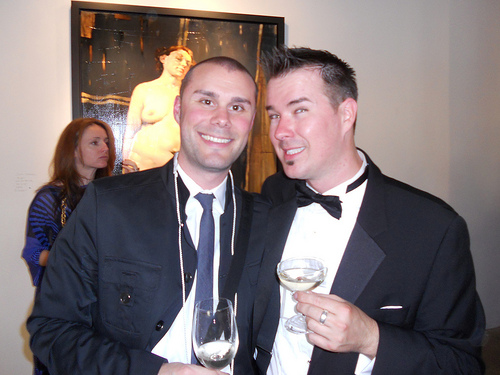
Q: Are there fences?
A: No, there are no fences.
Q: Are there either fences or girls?
A: No, there are no fences or girls.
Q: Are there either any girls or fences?
A: No, there are no fences or girls.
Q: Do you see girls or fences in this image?
A: No, there are no fences or girls.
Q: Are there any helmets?
A: No, there are no helmets.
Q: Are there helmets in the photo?
A: No, there are no helmets.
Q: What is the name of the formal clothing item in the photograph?
A: The clothing item is a suit.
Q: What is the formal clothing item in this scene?
A: The clothing item is a suit.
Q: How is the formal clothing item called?
A: The clothing item is a suit.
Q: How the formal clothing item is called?
A: The clothing item is a suit.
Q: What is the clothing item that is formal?
A: The clothing item is a suit.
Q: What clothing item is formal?
A: The clothing item is a suit.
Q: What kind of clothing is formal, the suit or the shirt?
A: The suit is formal.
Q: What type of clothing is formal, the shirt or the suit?
A: The suit is formal.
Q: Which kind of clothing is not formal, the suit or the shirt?
A: The shirt is not formal.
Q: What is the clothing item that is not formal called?
A: The clothing item is a shirt.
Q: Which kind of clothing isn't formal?
A: The clothing is a shirt.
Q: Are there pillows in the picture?
A: No, there are no pillows.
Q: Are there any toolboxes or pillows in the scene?
A: No, there are no pillows or toolboxes.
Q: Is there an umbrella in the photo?
A: No, there are no umbrellas.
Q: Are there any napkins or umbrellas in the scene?
A: No, there are no umbrellas or napkins.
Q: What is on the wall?
A: The picture is on the wall.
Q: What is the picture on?
A: The picture is on the wall.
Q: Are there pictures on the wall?
A: Yes, there is a picture on the wall.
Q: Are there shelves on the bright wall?
A: No, there is a picture on the wall.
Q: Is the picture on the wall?
A: Yes, the picture is on the wall.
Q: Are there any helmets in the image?
A: No, there are no helmets.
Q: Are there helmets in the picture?
A: No, there are no helmets.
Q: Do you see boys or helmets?
A: No, there are no helmets or boys.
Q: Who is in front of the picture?
A: The man is in front of the picture.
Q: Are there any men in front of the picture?
A: Yes, there is a man in front of the picture.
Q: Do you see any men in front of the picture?
A: Yes, there is a man in front of the picture.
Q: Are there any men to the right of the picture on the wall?
A: Yes, there is a man to the right of the picture.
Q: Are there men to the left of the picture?
A: No, the man is to the right of the picture.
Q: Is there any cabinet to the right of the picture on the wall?
A: No, there is a man to the right of the picture.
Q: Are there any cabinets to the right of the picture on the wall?
A: No, there is a man to the right of the picture.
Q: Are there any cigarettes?
A: No, there are no cigarettes.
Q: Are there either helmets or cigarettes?
A: No, there are no cigarettes or helmets.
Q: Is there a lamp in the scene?
A: No, there are no lamps.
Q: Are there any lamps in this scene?
A: No, there are no lamps.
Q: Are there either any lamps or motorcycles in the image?
A: No, there are no lamps or motorcycles.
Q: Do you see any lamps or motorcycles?
A: No, there are no lamps or motorcycles.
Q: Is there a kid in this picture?
A: No, there are no children.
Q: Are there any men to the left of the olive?
A: Yes, there is a man to the left of the olive.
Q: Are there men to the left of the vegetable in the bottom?
A: Yes, there is a man to the left of the olive.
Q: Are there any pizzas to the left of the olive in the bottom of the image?
A: No, there is a man to the left of the olive.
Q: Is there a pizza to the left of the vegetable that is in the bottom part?
A: No, there is a man to the left of the olive.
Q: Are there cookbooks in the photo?
A: No, there are no cookbooks.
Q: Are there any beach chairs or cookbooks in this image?
A: No, there are no cookbooks or beach chairs.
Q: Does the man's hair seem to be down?
A: Yes, the hair is down.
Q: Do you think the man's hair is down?
A: Yes, the hair is down.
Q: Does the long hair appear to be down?
A: Yes, the hair is down.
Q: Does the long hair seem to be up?
A: No, the hair is down.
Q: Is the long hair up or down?
A: The hair is down.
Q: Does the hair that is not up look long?
A: Yes, the hair is long.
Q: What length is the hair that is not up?
A: The hair is long.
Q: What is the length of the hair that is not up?
A: The hair is long.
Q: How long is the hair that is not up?
A: The hair is long.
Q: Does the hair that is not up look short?
A: No, the hair is long.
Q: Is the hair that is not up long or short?
A: The hair is long.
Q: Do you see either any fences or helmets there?
A: No, there are no fences or helmets.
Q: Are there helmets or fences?
A: No, there are no fences or helmets.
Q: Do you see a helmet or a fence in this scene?
A: No, there are no fences or helmets.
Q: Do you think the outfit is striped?
A: Yes, the outfit is striped.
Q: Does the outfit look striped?
A: Yes, the outfit is striped.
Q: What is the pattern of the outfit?
A: The outfit is striped.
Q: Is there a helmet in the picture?
A: No, there are no helmets.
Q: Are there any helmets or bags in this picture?
A: No, there are no helmets or bags.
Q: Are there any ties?
A: Yes, there is a tie.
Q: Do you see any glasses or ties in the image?
A: Yes, there is a tie.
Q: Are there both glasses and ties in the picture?
A: Yes, there are both a tie and glasses.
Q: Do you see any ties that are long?
A: Yes, there is a long tie.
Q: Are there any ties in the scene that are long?
A: Yes, there is a tie that is long.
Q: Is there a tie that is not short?
A: Yes, there is a long tie.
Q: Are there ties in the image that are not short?
A: Yes, there is a long tie.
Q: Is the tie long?
A: Yes, the tie is long.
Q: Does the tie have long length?
A: Yes, the tie is long.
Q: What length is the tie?
A: The tie is long.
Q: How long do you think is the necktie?
A: The necktie is long.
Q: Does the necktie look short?
A: No, the necktie is long.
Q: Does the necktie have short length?
A: No, the necktie is long.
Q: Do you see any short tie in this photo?
A: No, there is a tie but it is long.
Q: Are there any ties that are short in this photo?
A: No, there is a tie but it is long.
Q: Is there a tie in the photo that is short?
A: No, there is a tie but it is long.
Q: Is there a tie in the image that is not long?
A: No, there is a tie but it is long.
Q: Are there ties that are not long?
A: No, there is a tie but it is long.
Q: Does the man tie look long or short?
A: The necktie is long.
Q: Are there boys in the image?
A: No, there are no boys.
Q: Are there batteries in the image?
A: No, there are no batteries.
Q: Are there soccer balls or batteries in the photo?
A: No, there are no batteries or soccer balls.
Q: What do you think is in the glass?
A: The liquid is in the glass.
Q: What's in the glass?
A: The liquid is in the glass.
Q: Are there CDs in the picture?
A: No, there are no cds.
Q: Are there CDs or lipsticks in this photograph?
A: No, there are no CDs or lipsticks.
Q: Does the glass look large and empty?
A: Yes, the glass is large and empty.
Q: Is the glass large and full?
A: No, the glass is large but empty.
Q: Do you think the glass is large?
A: Yes, the glass is large.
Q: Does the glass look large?
A: Yes, the glass is large.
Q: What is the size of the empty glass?
A: The glass is large.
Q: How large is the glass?
A: The glass is large.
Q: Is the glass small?
A: No, the glass is large.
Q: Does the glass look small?
A: No, the glass is large.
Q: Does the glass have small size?
A: No, the glass is large.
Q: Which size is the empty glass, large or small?
A: The glass is large.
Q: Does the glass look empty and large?
A: Yes, the glass is empty and large.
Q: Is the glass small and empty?
A: No, the glass is empty but large.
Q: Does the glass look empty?
A: Yes, the glass is empty.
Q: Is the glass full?
A: No, the glass is empty.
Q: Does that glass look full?
A: No, the glass is empty.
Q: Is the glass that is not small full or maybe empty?
A: The glass is empty.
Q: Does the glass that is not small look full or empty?
A: The glass is empty.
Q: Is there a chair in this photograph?
A: No, there are no chairs.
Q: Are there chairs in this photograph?
A: No, there are no chairs.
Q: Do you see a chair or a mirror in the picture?
A: No, there are no chairs or mirrors.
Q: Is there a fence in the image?
A: No, there are no fences.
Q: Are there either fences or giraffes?
A: No, there are no fences or giraffes.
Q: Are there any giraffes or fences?
A: No, there are no fences or giraffes.